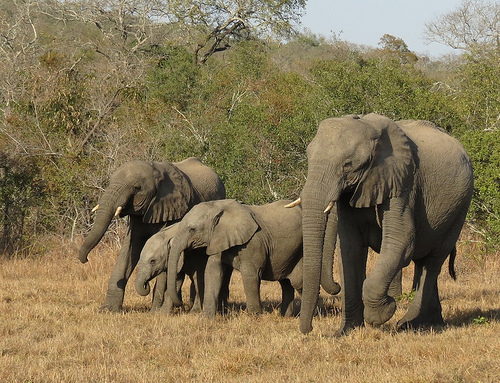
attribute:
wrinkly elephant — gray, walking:
[300, 111, 469, 327]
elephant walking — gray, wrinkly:
[172, 193, 348, 332]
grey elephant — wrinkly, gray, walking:
[77, 157, 238, 330]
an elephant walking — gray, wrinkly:
[127, 184, 315, 332]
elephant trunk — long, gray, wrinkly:
[270, 138, 367, 345]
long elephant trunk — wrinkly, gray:
[74, 176, 132, 264]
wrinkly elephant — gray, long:
[175, 182, 325, 322]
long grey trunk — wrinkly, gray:
[155, 224, 215, 321]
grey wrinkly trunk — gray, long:
[69, 183, 131, 262]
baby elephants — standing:
[130, 199, 319, 321]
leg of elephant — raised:
[354, 216, 410, 330]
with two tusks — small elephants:
[80, 197, 124, 227]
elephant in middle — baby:
[131, 190, 311, 330]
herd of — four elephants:
[85, 105, 482, 345]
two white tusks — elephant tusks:
[285, 181, 337, 222]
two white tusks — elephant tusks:
[281, 189, 347, 220]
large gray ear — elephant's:
[192, 183, 264, 257]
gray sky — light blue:
[312, 1, 461, 71]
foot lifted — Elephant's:
[357, 256, 411, 333]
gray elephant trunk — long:
[159, 232, 200, 311]